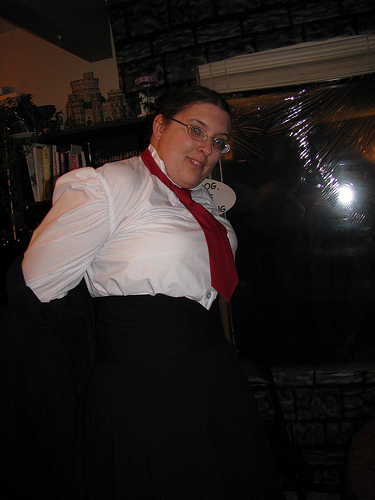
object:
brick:
[290, 383, 346, 423]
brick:
[190, 18, 293, 45]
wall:
[240, 73, 372, 353]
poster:
[202, 177, 237, 216]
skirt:
[52, 292, 276, 499]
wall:
[158, 42, 213, 70]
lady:
[0, 86, 239, 500]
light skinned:
[163, 133, 181, 173]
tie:
[171, 183, 238, 305]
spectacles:
[162, 116, 232, 154]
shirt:
[22, 144, 240, 304]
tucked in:
[43, 150, 252, 327]